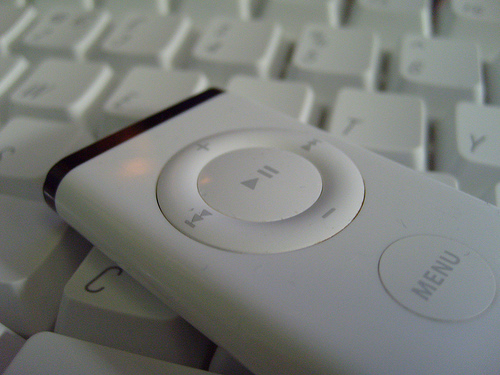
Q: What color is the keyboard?
A: White.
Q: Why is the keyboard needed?
A: To type.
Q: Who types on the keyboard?
A: The computer user.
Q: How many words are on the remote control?
A: One.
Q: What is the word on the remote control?
A: Menu.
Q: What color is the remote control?
A: White.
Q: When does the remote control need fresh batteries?
A: When they are dead.